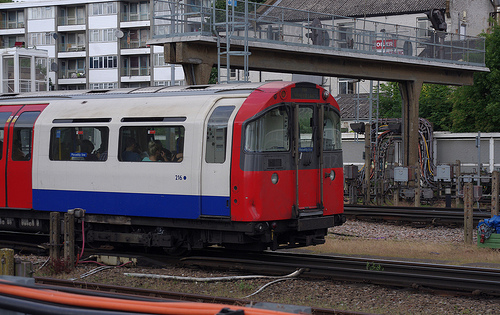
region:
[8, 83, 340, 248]
red, white, and blue train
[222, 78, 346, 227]
red front of train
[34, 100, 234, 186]
white middle of train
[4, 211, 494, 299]
tracks train is on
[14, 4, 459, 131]
building behind train tracks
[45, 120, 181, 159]
people sitting on train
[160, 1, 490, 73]
bridge walkway with fenced sides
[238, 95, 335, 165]
windows on first car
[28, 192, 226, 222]
blue streak along bottom of train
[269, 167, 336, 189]
lights on front of car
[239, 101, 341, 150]
A train windscreen in the photo.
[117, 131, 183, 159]
Passengers in the train.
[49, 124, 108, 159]
Train window in the photo.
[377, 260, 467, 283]
Railway track in the photo.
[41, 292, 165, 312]
Pipes in the photo.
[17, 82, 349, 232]
A train in the photo.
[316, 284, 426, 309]
Track ballast in the photo.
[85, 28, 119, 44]
Window in the photo.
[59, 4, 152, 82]
Building in the photo.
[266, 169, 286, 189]
Headlight in the photo.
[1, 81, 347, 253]
a red white and blue train car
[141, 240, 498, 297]
a set of train tracks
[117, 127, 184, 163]
a passenger train window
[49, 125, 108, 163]
a passenger train window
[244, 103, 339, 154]
a train engine windshield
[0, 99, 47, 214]
a red train entry exit door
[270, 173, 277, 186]
a train front headlight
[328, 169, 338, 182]
a train front headlight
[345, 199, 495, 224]
a set of train tracks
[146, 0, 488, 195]
an overhead walkway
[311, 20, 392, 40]
fencing along the balcony.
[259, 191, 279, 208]
red paint on the train.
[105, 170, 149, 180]
white paint on train.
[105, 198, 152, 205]
blue paint on train.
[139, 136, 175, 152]
window on the train.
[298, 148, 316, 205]
door on the train.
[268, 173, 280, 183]
light on the train.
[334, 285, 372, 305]
pebbles near the tracks.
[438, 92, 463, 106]
leaves on the trees.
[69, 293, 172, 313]
tubes near the train.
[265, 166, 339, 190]
Lights on front of train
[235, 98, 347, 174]
Windshield of the train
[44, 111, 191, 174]
Side windows of train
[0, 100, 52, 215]
Door of the train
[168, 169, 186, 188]
Number 216 on train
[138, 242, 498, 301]
Set of train tracks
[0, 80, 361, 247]
Red, white, and blue train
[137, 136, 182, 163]
People sitting on train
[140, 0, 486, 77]
Catwalk above the train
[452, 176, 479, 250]
Wooden post in ground